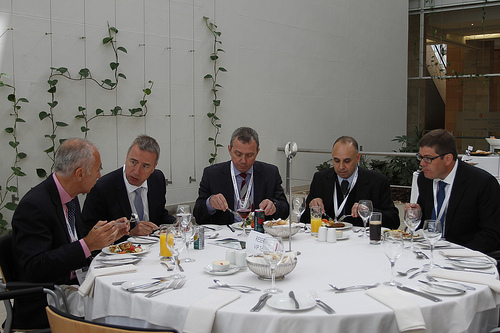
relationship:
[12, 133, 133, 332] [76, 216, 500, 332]
man at table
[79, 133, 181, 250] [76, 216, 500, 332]
man at table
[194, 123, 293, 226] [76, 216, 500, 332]
man at table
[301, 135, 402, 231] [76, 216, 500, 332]
man at table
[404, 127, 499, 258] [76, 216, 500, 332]
man at table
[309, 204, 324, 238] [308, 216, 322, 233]
glass of orange juice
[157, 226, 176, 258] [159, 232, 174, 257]
glass of orange juice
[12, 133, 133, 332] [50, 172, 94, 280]
man wearing shirt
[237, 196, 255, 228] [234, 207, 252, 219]
glass of wine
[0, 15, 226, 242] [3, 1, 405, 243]
ivy on wall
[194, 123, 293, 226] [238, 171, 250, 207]
man with tie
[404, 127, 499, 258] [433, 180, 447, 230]
man wearing tie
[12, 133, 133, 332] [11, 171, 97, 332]
man wearing suit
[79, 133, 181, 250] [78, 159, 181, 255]
man wearing suit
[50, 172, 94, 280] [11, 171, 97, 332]
shirt under suit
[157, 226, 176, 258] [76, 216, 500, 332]
glass on table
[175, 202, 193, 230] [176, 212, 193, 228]
glass of water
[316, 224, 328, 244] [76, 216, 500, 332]
shaker on table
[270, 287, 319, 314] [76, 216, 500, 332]
plate on table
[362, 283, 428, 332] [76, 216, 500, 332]
napkin on table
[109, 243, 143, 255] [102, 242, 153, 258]
food on plate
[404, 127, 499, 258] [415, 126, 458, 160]
man has hair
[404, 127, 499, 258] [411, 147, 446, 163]
man wearing glasses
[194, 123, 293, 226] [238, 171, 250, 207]
man wearing tie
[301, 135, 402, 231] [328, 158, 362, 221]
man wearing medal